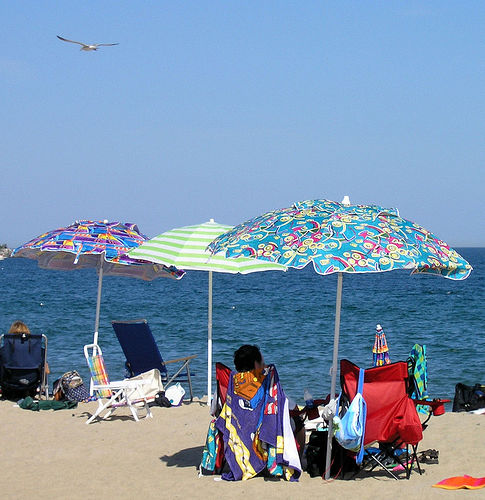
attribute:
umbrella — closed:
[368, 322, 392, 367]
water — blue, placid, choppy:
[0, 246, 484, 410]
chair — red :
[336, 355, 423, 460]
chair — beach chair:
[212, 360, 312, 478]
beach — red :
[10, 155, 470, 498]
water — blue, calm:
[11, 270, 469, 387]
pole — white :
[311, 269, 356, 420]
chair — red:
[99, 302, 208, 408]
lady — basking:
[0, 318, 50, 397]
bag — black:
[452, 381, 484, 410]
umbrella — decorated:
[238, 188, 458, 295]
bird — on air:
[56, 32, 121, 55]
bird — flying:
[55, 36, 125, 60]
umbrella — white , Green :
[129, 213, 288, 428]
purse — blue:
[334, 368, 368, 463]